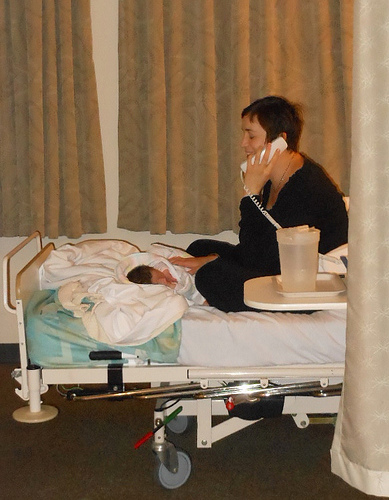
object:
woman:
[169, 93, 350, 315]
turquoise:
[37, 237, 184, 348]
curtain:
[0, 0, 109, 241]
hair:
[239, 92, 306, 156]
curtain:
[116, 1, 359, 236]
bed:
[15, 232, 350, 492]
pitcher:
[274, 223, 319, 294]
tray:
[270, 270, 345, 301]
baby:
[127, 262, 216, 308]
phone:
[236, 134, 347, 280]